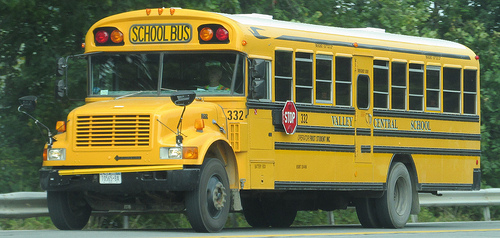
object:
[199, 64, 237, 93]
man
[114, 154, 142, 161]
arrow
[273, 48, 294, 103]
window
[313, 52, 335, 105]
window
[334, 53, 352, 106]
window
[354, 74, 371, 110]
window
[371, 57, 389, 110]
window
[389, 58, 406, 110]
window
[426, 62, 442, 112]
window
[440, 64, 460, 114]
window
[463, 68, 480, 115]
window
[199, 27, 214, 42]
light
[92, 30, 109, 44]
light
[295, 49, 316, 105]
open window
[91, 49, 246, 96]
windshield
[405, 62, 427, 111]
passenger window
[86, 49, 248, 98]
driver's side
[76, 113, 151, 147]
grill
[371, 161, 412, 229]
tire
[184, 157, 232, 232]
tire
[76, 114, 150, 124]
lines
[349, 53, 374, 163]
door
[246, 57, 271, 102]
window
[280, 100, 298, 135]
sign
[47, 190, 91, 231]
tire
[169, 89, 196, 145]
mirror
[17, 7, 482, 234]
bus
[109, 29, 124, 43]
lights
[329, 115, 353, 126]
writing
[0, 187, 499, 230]
guard rail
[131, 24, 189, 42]
words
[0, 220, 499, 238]
road